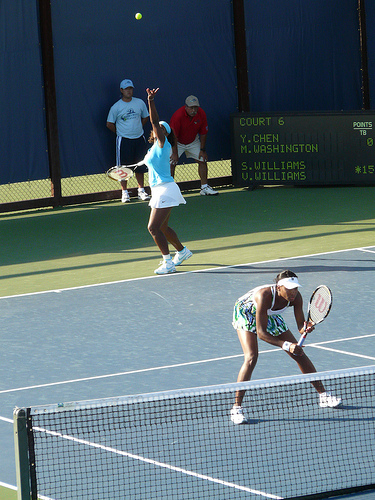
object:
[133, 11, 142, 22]
ball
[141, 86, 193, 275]
tennis player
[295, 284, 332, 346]
racket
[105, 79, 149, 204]
man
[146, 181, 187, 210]
skirt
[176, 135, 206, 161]
white shorts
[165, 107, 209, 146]
red shirt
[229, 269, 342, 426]
woman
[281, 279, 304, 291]
visor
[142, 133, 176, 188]
shirt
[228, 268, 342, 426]
tennis player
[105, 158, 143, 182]
tennis racket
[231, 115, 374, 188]
display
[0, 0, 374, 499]
tennis court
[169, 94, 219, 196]
man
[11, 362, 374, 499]
net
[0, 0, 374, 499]
tennis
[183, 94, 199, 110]
cap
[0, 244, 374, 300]
baseline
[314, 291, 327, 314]
logo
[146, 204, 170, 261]
legs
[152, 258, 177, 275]
shoes